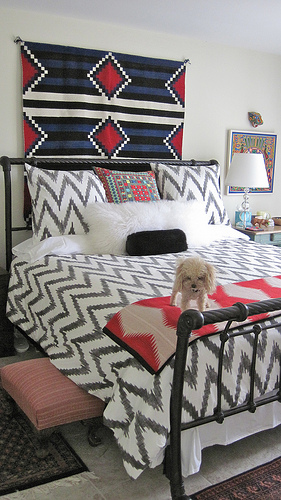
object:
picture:
[226, 130, 277, 193]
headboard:
[2, 151, 224, 260]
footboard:
[162, 305, 267, 360]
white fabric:
[82, 196, 205, 232]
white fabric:
[8, 234, 91, 262]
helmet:
[9, 40, 190, 156]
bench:
[0, 354, 107, 463]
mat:
[0, 387, 92, 494]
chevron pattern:
[87, 49, 134, 105]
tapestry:
[18, 36, 190, 226]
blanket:
[102, 275, 279, 375]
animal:
[169, 257, 217, 312]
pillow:
[150, 156, 226, 226]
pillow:
[93, 166, 156, 204]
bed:
[0, 155, 280, 500]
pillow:
[124, 229, 188, 256]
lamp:
[225, 149, 273, 228]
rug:
[186, 456, 281, 500]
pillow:
[24, 160, 109, 245]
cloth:
[17, 37, 185, 222]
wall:
[1, 1, 280, 277]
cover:
[6, 237, 280, 479]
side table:
[234, 214, 279, 241]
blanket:
[6, 238, 280, 482]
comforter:
[6, 238, 280, 479]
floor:
[2, 464, 121, 500]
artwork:
[171, 314, 263, 498]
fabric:
[13, 201, 250, 267]